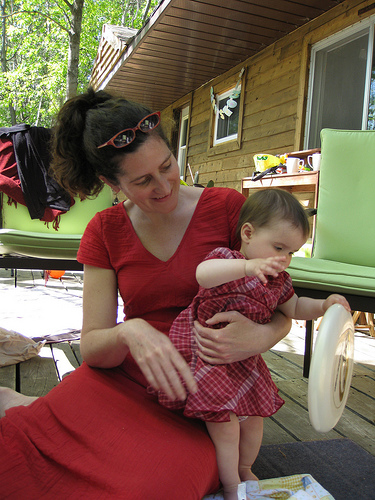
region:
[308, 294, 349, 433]
baby is hold a frisbee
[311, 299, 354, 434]
the frisbee is white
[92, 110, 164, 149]
a pair of red glasses on top of woman's head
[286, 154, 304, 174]
a white mug on the table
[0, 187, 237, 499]
woman is wearing a red dress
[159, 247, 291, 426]
baby is wearing a red dress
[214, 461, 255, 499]
the baby is barefoot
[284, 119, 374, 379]
a green chair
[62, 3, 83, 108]
the trunk of a tree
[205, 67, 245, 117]
decorations on top of the window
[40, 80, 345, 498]
people sitting outside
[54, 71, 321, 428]
a woman sitting outside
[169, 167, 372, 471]
a baby standing outside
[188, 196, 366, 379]
a baby holding a freesbee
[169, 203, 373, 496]
a baby holding a white freesbee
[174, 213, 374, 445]
a baby weairng jacket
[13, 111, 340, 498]
a woman wearing a jacket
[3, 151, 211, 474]
a woman wearing a red jacket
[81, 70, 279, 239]
a woman with glass on head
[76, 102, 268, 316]
a woman with sunglasses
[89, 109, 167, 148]
a woman's red sunglasses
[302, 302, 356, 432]
a white Frisbee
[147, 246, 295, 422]
a girl's red and white dress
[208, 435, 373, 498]
part of a gray mat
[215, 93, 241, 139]
a window of a building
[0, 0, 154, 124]
part of a green tree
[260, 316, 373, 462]
part of a wooden deck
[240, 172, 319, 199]
part of a wooden table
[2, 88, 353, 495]
Woman holding a baby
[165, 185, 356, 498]
Baby holding a white frisbee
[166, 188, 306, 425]
Baby girl wearing a red dress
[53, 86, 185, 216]
Woman with sunglasses on top of her head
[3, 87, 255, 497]
Woman wearing a red V-neck dress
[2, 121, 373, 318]
Two lime green fabric chairs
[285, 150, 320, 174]
Two white coffee mugs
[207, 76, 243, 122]
Paper letters hanging on a window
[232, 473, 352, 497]
The corner of a baby blanket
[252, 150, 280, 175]
Yellow bowl on a wood table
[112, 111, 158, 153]
glasses on woman's head.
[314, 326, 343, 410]
frisbee in child's hand.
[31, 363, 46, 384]
deck made of wood.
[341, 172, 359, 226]
chair on the deck.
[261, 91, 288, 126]
wall made of wood.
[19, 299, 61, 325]
rug on the deck.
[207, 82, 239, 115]
decoration over the window.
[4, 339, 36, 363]
blanket on the ground.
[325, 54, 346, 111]
window screen on wall.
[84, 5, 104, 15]
leaves on the tree.